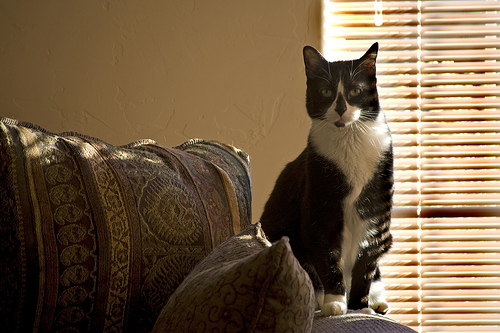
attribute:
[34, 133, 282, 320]
pillow — orange, burgundy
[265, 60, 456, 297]
cat — black, white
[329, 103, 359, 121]
nose — black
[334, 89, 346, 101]
spot — black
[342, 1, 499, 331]
shades — light brown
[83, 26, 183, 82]
plaster wall — white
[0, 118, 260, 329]
couch fabric — multi colored